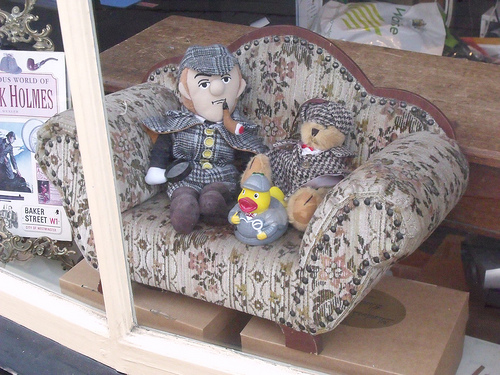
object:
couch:
[34, 23, 473, 358]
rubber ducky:
[227, 172, 291, 248]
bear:
[237, 97, 361, 234]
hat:
[287, 98, 357, 159]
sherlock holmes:
[138, 41, 268, 234]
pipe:
[221, 99, 245, 139]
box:
[238, 275, 474, 374]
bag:
[308, 0, 463, 57]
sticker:
[337, 287, 405, 331]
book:
[0, 50, 74, 243]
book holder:
[1, 0, 79, 271]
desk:
[95, 12, 498, 242]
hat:
[179, 45, 237, 77]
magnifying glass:
[250, 218, 265, 234]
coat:
[142, 105, 266, 186]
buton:
[202, 126, 217, 137]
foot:
[279, 324, 326, 357]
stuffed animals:
[136, 44, 356, 246]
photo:
[1, 0, 500, 373]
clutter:
[289, 2, 499, 67]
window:
[0, 0, 498, 374]